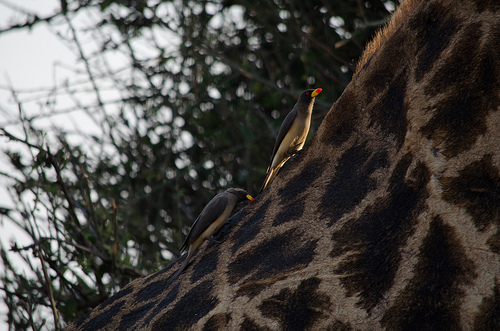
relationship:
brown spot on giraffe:
[225, 223, 317, 292] [64, 2, 499, 326]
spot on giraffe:
[465, 276, 500, 331] [64, 2, 499, 326]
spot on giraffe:
[465, 286, 497, 327] [64, 2, 499, 326]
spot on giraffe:
[425, 145, 498, 235] [64, 2, 499, 326]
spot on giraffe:
[254, 271, 334, 328] [64, 2, 499, 326]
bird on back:
[179, 185, 255, 274] [64, 0, 499, 331]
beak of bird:
[244, 190, 256, 202] [177, 181, 258, 265]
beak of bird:
[307, 90, 324, 102] [249, 76, 329, 191]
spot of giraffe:
[222, 225, 320, 299] [64, 2, 499, 326]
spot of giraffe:
[272, 151, 326, 222] [107, 5, 496, 327]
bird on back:
[241, 80, 335, 180] [20, 27, 370, 322]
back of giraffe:
[20, 27, 370, 322] [4, 6, 491, 328]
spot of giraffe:
[386, 209, 476, 329] [353, 165, 447, 223]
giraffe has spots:
[64, 2, 499, 326] [92, 18, 478, 324]